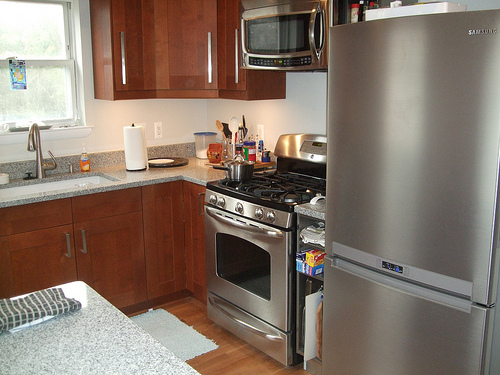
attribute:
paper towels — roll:
[116, 120, 154, 174]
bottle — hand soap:
[74, 150, 94, 178]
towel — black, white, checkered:
[0, 281, 82, 339]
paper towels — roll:
[118, 116, 154, 171]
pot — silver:
[212, 152, 255, 191]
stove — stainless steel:
[193, 132, 329, 365]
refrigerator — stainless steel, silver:
[316, 11, 498, 372]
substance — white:
[196, 145, 211, 158]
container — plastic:
[189, 128, 219, 163]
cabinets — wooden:
[0, 192, 142, 298]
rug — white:
[137, 301, 221, 367]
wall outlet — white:
[151, 117, 170, 143]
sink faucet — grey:
[22, 120, 51, 184]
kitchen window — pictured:
[1, 2, 88, 134]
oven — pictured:
[202, 202, 298, 349]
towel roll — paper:
[121, 121, 151, 171]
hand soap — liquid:
[76, 140, 92, 172]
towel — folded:
[1, 285, 81, 333]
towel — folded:
[7, 311, 57, 334]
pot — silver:
[207, 156, 254, 185]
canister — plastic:
[192, 130, 218, 160]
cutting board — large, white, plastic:
[302, 290, 320, 362]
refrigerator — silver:
[320, 6, 483, 373]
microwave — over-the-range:
[237, 1, 327, 72]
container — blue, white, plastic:
[192, 130, 218, 160]